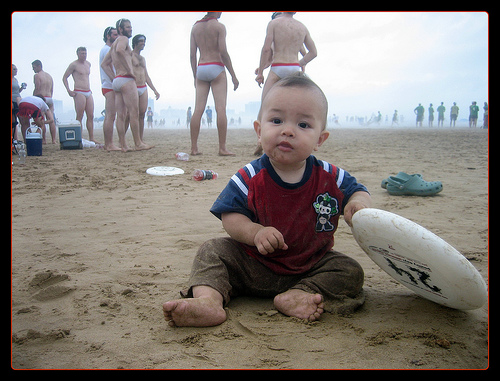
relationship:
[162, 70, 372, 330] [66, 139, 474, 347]
baby at beach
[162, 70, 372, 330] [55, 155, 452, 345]
baby at beach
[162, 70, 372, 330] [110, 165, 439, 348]
baby at beach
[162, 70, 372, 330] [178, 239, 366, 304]
baby wearing pants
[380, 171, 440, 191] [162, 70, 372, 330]
shoes behind baby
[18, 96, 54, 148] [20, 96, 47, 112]
person wearing a shirt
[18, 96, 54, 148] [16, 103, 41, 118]
person wearing shorts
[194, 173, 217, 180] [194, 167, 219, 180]
drink inside a bottle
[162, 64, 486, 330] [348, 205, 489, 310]
baby holding frisbee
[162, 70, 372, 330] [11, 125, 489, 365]
baby sitting on sand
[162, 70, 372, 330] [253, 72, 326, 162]
baby has a head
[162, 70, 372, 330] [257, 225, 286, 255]
baby has a hand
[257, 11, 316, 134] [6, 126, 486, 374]
person standing on beach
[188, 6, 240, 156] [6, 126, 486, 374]
man standing on beach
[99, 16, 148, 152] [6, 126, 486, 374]
guy standing on beach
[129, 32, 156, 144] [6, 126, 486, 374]
person standing on beach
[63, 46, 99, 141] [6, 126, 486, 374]
person standing on beach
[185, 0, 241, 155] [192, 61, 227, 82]
man wearing a swimsuit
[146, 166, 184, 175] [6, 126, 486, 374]
disc on beach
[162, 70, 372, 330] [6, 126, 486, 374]
baby sitting on beach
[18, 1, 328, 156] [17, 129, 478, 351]
people standing on beach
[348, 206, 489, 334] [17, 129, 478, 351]
frisbee on beach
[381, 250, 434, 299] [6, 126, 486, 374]
logo on beach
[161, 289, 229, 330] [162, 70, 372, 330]
foot of baby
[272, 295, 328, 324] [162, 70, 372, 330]
foot of baby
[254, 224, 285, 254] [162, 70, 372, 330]
hand of baby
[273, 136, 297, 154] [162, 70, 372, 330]
mouth of baby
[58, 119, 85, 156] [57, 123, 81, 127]
cooler with lid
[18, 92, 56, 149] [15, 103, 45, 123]
person in shorts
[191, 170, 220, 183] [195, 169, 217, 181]
bottle of liquid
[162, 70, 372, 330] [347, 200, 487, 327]
baby holding frisbee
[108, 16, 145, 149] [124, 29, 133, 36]
guy with beard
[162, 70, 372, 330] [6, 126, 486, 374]
baby on beach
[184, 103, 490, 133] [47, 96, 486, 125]
people in ocean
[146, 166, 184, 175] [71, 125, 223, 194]
disc on sand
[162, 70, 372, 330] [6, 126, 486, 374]
baby at beach